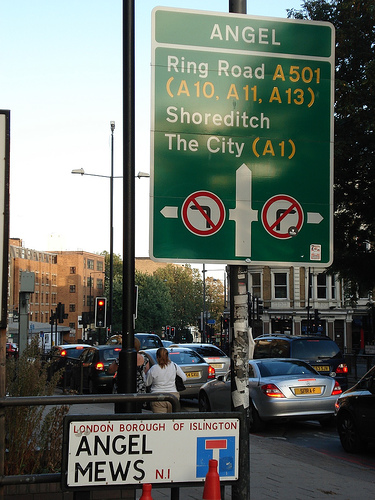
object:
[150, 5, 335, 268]
label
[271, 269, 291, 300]
window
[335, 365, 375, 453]
car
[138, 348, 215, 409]
car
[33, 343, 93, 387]
car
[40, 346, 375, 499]
road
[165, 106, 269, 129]
shoreditch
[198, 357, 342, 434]
car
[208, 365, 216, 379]
tail light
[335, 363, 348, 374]
tail light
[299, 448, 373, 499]
ground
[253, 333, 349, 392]
car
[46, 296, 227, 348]
intersection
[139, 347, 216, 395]
car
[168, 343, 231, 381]
car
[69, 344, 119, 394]
car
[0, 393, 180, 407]
railing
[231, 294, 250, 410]
tape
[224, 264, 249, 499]
pole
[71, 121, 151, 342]
lamp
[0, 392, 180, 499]
fence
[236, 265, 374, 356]
building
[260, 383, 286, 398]
light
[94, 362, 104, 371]
light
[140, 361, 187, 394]
white shirt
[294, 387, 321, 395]
license plate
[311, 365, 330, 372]
license plate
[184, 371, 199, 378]
license plate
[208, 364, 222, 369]
license plate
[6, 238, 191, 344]
building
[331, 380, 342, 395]
tail light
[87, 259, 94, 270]
window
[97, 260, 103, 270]
window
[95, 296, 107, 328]
traffic light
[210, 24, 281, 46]
word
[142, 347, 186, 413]
girl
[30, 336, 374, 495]
street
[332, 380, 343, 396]
light